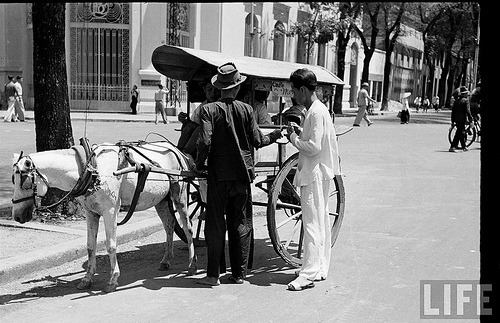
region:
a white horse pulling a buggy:
[12, 137, 202, 289]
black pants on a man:
[198, 172, 257, 290]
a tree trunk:
[23, 2, 94, 216]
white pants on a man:
[297, 166, 333, 288]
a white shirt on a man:
[296, 96, 340, 193]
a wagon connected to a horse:
[138, 27, 345, 271]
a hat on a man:
[214, 59, 249, 95]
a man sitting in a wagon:
[183, 68, 212, 162]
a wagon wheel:
[268, 147, 341, 274]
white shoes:
[291, 269, 316, 293]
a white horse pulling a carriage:
[10, 137, 198, 304]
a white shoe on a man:
[291, 277, 318, 289]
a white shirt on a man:
[293, 101, 350, 185]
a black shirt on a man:
[196, 97, 278, 184]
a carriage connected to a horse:
[148, 26, 357, 270]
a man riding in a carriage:
[184, 72, 223, 158]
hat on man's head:
[207, 57, 251, 94]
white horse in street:
[12, 140, 209, 297]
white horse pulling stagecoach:
[6, 137, 205, 294]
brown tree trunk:
[26, 1, 102, 223]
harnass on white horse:
[3, 137, 185, 226]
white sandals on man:
[281, 268, 321, 294]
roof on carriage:
[145, 32, 348, 98]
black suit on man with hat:
[186, 94, 284, 280]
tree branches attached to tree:
[349, 22, 374, 58]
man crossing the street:
[350, 77, 379, 134]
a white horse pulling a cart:
[13, 140, 200, 292]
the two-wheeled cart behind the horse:
[147, 41, 344, 261]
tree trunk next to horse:
[30, 4, 83, 220]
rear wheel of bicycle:
[445, 111, 484, 150]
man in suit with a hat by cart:
[200, 61, 281, 286]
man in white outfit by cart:
[285, 70, 340, 290]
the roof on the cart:
[149, 45, 346, 82]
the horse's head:
[10, 153, 46, 221]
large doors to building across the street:
[74, 28, 130, 111]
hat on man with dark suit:
[210, 63, 246, 91]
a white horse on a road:
[9, 140, 196, 290]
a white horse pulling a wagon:
[14, 43, 344, 299]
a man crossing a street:
[354, 82, 371, 132]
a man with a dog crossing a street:
[351, 78, 416, 130]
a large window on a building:
[71, 2, 128, 109]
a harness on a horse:
[10, 157, 44, 225]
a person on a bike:
[444, 86, 485, 148]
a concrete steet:
[354, 161, 464, 296]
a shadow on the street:
[7, 218, 304, 305]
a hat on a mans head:
[210, 61, 245, 96]